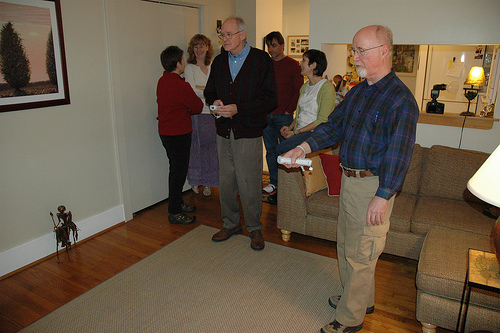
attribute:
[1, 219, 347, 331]
carpet — grey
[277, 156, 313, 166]
wii remote — white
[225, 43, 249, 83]
shirt — blue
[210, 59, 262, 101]
sweater — plaid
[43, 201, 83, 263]
statue — metal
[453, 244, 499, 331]
table — small 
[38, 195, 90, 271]
stauette — small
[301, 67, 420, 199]
dress shirt — blue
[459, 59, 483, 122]
lamp — on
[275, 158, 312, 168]
controller — video game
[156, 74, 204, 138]
shirt — red 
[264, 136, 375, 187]
remote — game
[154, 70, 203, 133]
sweater — red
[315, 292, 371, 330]
shoes — brown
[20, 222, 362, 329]
rug — gray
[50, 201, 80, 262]
statue — small, metal